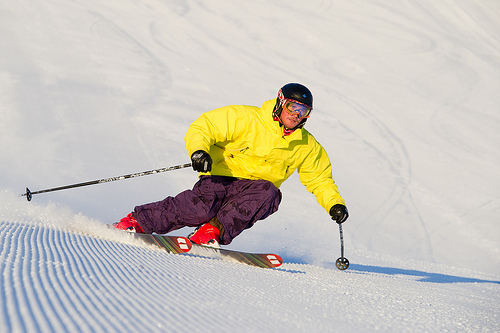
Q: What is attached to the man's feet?
A: Skis.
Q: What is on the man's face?
A: Goggles.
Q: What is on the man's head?
A: A helmet.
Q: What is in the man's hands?
A: Ski poles.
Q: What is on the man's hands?
A: Gloves.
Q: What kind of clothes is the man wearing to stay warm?
A: A yellow jacket and purple pants.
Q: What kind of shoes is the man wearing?
A: Red ski boots.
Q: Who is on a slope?
A: A skier.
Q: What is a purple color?
A: Pants.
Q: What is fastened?
A: A jacket.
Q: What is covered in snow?
A: A hill.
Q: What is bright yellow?
A: Ski jacket.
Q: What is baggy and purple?
A: Ski pants.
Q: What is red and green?
A: Skis.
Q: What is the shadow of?
A: A skier.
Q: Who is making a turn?
A: A skier.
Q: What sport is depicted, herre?
A: Skiing.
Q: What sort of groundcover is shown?
A: Snow.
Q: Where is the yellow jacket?
A: On a male skier, swooshing downhill.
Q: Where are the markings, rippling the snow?
A: To the right of the skier.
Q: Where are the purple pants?
A: On the skier?.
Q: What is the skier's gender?
A: Male.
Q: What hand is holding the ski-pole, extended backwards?
A: The right hand.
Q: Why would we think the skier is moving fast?
A: He is kicking up lots of snow and leaning heavily to the right.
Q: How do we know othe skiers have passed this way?
A: There are numerous trails, behind the skier.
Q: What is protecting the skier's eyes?
A: Goggles.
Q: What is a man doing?
A: Skiing.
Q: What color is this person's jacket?
A: Yellow.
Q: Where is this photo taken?
A: On a ski slope.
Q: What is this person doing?
A: Skiing.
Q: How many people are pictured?
A: One.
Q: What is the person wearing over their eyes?
A: Goggles.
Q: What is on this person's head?
A: Helmet.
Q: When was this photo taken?
A: During the daytime.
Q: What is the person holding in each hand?
A: Ski poles.